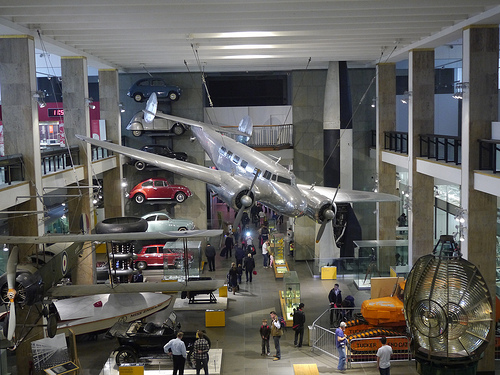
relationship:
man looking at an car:
[194, 331, 209, 374] [107, 319, 207, 367]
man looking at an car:
[163, 332, 187, 374] [107, 319, 207, 367]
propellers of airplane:
[231, 167, 341, 244] [74, 91, 402, 243]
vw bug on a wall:
[125, 76, 179, 103] [118, 65, 454, 239]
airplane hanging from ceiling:
[74, 91, 402, 243] [2, 2, 497, 73]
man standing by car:
[163, 332, 187, 374] [113, 321, 202, 357]